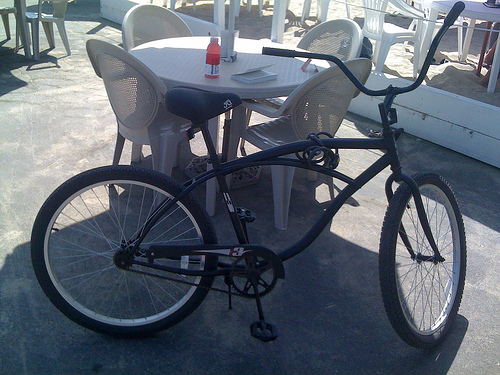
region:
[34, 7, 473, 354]
this is a bicylcle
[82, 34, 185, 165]
this is a chair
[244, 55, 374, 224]
this is a chair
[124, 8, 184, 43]
this is a chair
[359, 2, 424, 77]
this is a chair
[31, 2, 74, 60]
this is a chair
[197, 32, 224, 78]
this is a bottle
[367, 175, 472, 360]
this is a wheel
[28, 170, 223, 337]
this is a wheel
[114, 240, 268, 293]
this is a chain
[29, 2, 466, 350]
a black bicycle propped on a stand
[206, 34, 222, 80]
a red bottle on a table with a white lid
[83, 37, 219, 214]
a white patio chair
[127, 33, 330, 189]
a white round patio table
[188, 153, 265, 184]
a metal stand on the ground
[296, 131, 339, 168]
metal wires around a bike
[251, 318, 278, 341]
a black bike's pedal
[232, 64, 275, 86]
a white book on a patio table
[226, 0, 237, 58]
a white metal pole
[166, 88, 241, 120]
a black seat on a bicycle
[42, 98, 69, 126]
this is the floor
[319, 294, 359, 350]
the floor is clean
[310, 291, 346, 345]
the floor is grey in color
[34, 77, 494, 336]
this is a bicycle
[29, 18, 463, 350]
the bicycle is big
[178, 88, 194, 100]
the seat is black in color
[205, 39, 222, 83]
this is a bottle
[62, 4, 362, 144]
these are some chairs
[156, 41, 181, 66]
this is a table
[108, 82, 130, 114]
the chair is white in color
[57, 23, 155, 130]
White chair pushed up to table.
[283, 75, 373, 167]
White chair pushed up to table.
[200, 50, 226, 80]
Pink drink sitting on table.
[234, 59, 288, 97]
Book sitting on table.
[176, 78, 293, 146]
Black seat on bike.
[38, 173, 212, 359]
Back tire on bike is black.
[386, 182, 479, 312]
Front tire on bike is black.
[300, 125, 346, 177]
Black bike lock on bike.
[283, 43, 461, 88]
Black handle bars on bike.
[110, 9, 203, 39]
White chair pushed up to table.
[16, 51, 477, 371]
the bike is leaning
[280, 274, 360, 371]
shadow is on the ground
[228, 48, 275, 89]
book is on the table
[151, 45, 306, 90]
shadow table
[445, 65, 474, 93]
the sand is white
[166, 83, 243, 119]
the seat is black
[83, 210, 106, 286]
the spokes are thin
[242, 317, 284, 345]
the pedal is black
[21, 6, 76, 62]
the chair is plastic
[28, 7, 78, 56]
the chair is white